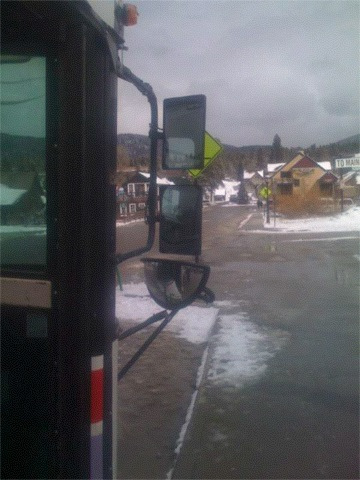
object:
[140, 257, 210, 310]
mirror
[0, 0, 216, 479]
bus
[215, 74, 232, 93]
cloud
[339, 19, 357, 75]
sky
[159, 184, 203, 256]
mirror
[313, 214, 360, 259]
ground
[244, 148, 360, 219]
houses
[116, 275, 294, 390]
slush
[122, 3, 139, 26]
light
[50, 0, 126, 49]
roof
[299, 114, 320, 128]
clouds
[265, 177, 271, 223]
street light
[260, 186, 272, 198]
sign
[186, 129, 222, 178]
sign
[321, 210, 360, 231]
sidewalk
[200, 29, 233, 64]
sky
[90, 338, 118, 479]
design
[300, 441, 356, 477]
street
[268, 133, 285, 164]
trees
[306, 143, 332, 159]
trees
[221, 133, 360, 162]
hills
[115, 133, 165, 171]
hills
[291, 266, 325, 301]
water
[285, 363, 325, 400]
street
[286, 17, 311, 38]
clods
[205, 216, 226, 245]
street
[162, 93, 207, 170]
mirror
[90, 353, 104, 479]
stripe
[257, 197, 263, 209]
couple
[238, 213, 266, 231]
sidewalk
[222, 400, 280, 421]
wet street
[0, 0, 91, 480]
bus door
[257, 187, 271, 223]
caution sign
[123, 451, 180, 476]
street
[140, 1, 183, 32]
sky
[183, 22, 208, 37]
clouds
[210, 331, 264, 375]
snow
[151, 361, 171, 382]
ice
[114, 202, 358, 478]
road